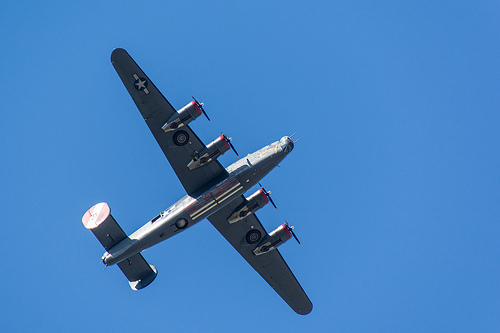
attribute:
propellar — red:
[282, 217, 304, 244]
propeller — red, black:
[209, 113, 271, 160]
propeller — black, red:
[216, 127, 245, 160]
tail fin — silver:
[75, 202, 158, 295]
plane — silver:
[51, 23, 391, 330]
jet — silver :
[46, 28, 349, 322]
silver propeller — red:
[177, 73, 230, 154]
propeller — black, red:
[282, 216, 304, 248]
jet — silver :
[82, 46, 314, 314]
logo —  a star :
[134, 75, 150, 91]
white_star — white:
[122, 72, 158, 96]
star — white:
[130, 75, 148, 89]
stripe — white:
[184, 181, 238, 217]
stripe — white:
[190, 185, 242, 222]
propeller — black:
[185, 92, 210, 121]